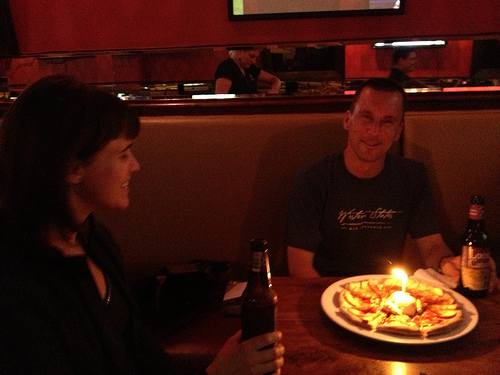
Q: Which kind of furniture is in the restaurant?
A: The piece of furniture is a table.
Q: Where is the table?
A: The table is in the restaurant.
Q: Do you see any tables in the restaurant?
A: Yes, there is a table in the restaurant.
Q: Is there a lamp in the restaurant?
A: No, there is a table in the restaurant.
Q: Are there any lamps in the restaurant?
A: No, there is a table in the restaurant.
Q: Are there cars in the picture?
A: No, there are no cars.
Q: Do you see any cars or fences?
A: No, there are no cars or fences.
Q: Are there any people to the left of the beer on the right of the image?
A: Yes, there is a person to the left of the beer.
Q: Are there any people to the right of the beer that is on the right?
A: No, the person is to the left of the beer.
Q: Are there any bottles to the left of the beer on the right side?
A: No, there is a person to the left of the beer.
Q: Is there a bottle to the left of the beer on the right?
A: No, there is a person to the left of the beer.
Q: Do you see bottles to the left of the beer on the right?
A: No, there is a person to the left of the beer.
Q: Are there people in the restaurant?
A: Yes, there is a person in the restaurant.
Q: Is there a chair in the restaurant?
A: No, there is a person in the restaurant.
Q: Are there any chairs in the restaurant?
A: No, there is a person in the restaurant.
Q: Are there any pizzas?
A: Yes, there is a pizza.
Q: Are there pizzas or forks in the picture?
A: Yes, there is a pizza.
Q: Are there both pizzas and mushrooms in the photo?
A: No, there is a pizza but no mushrooms.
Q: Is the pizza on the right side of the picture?
A: Yes, the pizza is on the right of the image.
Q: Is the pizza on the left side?
A: No, the pizza is on the right of the image.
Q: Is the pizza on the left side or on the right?
A: The pizza is on the right of the image.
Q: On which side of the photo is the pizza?
A: The pizza is on the right of the image.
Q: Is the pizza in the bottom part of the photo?
A: Yes, the pizza is in the bottom of the image.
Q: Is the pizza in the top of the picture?
A: No, the pizza is in the bottom of the image.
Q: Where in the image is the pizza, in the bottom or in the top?
A: The pizza is in the bottom of the image.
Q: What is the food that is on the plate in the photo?
A: The food is a pizza.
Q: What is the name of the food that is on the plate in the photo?
A: The food is a pizza.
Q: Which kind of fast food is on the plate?
A: The food is a pizza.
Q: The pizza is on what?
A: The pizza is on the plate.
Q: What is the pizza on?
A: The pizza is on the plate.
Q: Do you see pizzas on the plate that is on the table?
A: Yes, there is a pizza on the plate.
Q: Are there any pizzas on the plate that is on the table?
A: Yes, there is a pizza on the plate.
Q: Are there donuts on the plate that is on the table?
A: No, there is a pizza on the plate.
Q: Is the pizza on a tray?
A: No, the pizza is on the plate.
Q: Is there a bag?
A: No, there are no bags.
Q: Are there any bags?
A: No, there are no bags.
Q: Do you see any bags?
A: No, there are no bags.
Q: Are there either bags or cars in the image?
A: No, there are no bags or cars.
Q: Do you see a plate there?
A: Yes, there is a plate.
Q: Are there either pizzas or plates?
A: Yes, there is a plate.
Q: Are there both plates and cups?
A: No, there is a plate but no cups.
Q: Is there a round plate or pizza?
A: Yes, there is a round plate.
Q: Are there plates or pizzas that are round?
A: Yes, the plate is round.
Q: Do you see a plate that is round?
A: Yes, there is a round plate.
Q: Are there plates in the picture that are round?
A: Yes, there is a plate that is round.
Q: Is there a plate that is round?
A: Yes, there is a plate that is round.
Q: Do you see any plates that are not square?
A: Yes, there is a round plate.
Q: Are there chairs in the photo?
A: No, there are no chairs.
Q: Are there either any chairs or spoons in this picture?
A: No, there are no chairs or spoons.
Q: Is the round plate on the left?
A: No, the plate is on the right of the image.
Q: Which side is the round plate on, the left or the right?
A: The plate is on the right of the image.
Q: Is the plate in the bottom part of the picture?
A: Yes, the plate is in the bottom of the image.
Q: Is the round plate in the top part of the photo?
A: No, the plate is in the bottom of the image.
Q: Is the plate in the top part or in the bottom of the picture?
A: The plate is in the bottom of the image.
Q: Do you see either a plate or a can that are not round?
A: No, there is a plate but it is round.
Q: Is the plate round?
A: Yes, the plate is round.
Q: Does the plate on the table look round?
A: Yes, the plate is round.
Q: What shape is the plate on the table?
A: The plate is round.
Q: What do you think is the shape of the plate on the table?
A: The plate is round.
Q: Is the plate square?
A: No, the plate is round.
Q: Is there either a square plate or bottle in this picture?
A: No, there is a plate but it is round.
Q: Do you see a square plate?
A: No, there is a plate but it is round.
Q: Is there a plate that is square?
A: No, there is a plate but it is round.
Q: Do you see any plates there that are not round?
A: No, there is a plate but it is round.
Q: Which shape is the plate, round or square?
A: The plate is round.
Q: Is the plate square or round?
A: The plate is round.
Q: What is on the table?
A: The plate is on the table.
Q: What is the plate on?
A: The plate is on the table.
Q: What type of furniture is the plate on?
A: The plate is on the table.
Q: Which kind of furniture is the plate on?
A: The plate is on the table.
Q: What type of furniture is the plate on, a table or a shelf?
A: The plate is on a table.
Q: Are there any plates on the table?
A: Yes, there is a plate on the table.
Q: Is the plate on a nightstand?
A: No, the plate is on the table.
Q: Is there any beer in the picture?
A: Yes, there is beer.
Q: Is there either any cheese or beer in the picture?
A: Yes, there is beer.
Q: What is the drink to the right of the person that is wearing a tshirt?
A: The drink is beer.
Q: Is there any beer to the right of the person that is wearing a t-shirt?
A: Yes, there is beer to the right of the person.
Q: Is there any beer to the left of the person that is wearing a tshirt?
A: No, the beer is to the right of the person.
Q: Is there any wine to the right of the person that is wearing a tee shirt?
A: No, there is beer to the right of the person.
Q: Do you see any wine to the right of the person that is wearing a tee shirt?
A: No, there is beer to the right of the person.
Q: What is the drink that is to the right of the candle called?
A: The drink is beer.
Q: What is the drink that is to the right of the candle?
A: The drink is beer.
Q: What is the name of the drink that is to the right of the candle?
A: The drink is beer.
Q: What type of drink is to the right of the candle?
A: The drink is beer.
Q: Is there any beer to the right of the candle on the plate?
A: Yes, there is beer to the right of the candle.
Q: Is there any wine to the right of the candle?
A: No, there is beer to the right of the candle.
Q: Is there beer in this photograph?
A: Yes, there is beer.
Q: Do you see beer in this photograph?
A: Yes, there is beer.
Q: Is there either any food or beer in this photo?
A: Yes, there is beer.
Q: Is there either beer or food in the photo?
A: Yes, there is beer.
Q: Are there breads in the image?
A: No, there are no breads.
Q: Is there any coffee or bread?
A: No, there are no breads or coffee.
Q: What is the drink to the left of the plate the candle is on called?
A: The drink is beer.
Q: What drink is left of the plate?
A: The drink is beer.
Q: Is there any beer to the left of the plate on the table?
A: Yes, there is beer to the left of the plate.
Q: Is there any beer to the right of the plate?
A: No, the beer is to the left of the plate.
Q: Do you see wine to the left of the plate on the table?
A: No, there is beer to the left of the plate.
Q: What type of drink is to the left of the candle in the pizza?
A: The drink is beer.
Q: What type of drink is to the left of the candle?
A: The drink is beer.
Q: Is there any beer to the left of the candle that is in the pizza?
A: Yes, there is beer to the left of the candle.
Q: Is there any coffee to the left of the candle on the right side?
A: No, there is beer to the left of the candle.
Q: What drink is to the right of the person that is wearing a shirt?
A: The drink is beer.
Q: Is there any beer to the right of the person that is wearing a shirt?
A: Yes, there is beer to the right of the person.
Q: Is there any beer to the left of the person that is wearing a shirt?
A: No, the beer is to the right of the person.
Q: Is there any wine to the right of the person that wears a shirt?
A: No, there is beer to the right of the person.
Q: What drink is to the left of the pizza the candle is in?
A: The drink is beer.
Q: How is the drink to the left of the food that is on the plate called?
A: The drink is beer.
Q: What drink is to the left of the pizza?
A: The drink is beer.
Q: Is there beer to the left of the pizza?
A: Yes, there is beer to the left of the pizza.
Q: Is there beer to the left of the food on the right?
A: Yes, there is beer to the left of the pizza.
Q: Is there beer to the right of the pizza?
A: No, the beer is to the left of the pizza.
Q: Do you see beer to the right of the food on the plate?
A: No, the beer is to the left of the pizza.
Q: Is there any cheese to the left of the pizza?
A: No, there is beer to the left of the pizza.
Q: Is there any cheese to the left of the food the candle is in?
A: No, there is beer to the left of the pizza.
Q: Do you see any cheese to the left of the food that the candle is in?
A: No, there is beer to the left of the pizza.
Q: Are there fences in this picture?
A: No, there are no fences.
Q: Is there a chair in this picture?
A: No, there are no chairs.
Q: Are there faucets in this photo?
A: No, there are no faucets.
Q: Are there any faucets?
A: No, there are no faucets.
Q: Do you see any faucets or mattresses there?
A: No, there are no faucets or mattresses.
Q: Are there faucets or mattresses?
A: No, there are no faucets or mattresses.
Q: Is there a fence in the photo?
A: No, there are no fences.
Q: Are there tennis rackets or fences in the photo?
A: No, there are no fences or tennis rackets.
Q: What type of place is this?
A: It is a restaurant.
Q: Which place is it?
A: It is a restaurant.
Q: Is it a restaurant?
A: Yes, it is a restaurant.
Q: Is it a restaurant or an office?
A: It is a restaurant.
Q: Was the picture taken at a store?
A: No, the picture was taken in a restaurant.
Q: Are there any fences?
A: No, there are no fences.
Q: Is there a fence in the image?
A: No, there are no fences.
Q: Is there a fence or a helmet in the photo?
A: No, there are no fences or helmets.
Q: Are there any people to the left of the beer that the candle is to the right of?
A: Yes, there is a person to the left of the beer.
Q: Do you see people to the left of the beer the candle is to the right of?
A: Yes, there is a person to the left of the beer.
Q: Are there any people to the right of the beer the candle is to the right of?
A: No, the person is to the left of the beer.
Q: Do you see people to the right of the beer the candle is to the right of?
A: No, the person is to the left of the beer.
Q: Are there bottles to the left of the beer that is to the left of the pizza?
A: No, there is a person to the left of the beer.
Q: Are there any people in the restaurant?
A: Yes, there is a person in the restaurant.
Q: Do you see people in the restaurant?
A: Yes, there is a person in the restaurant.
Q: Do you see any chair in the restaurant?
A: No, there is a person in the restaurant.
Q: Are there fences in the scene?
A: No, there are no fences.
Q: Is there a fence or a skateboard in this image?
A: No, there are no fences or skateboards.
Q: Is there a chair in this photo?
A: No, there are no chairs.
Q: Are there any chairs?
A: No, there are no chairs.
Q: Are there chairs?
A: No, there are no chairs.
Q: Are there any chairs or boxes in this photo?
A: No, there are no chairs or boxes.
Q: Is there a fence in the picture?
A: No, there are no fences.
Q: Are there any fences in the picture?
A: No, there are no fences.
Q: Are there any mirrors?
A: Yes, there is a mirror.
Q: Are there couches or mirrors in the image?
A: Yes, there is a mirror.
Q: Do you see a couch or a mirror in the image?
A: Yes, there is a mirror.